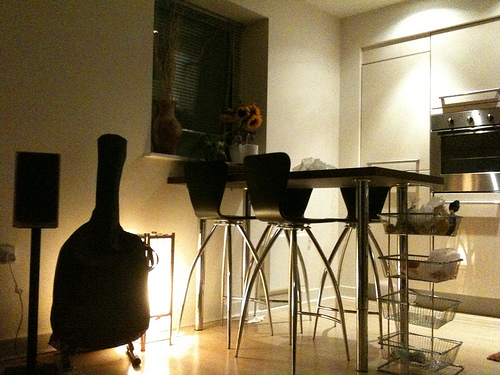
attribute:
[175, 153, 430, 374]
table — small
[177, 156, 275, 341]
stool — high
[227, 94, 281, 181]
flower — yellow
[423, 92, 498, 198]
oven — gray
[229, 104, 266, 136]
flower — yellow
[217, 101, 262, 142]
sunflowers — large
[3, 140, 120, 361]
speaker — black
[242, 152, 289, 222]
back seat — black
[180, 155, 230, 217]
back seat — black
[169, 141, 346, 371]
chairs — black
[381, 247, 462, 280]
basket — small, wire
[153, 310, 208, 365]
reflection — bright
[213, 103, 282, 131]
flower — yellow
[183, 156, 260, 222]
seat — black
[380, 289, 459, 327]
basket — small, wire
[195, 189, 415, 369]
legs — metal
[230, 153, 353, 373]
stool — high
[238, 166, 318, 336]
stool — high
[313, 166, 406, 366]
stool — high